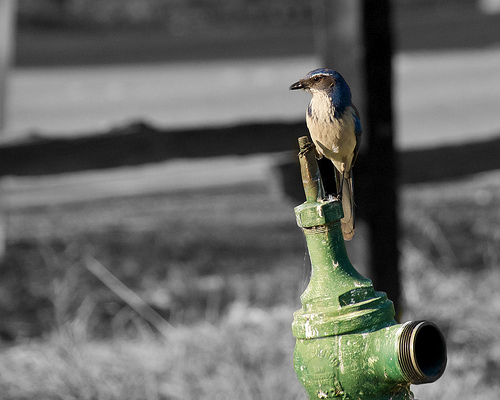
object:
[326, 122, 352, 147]
feathers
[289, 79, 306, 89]
beak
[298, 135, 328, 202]
nozzle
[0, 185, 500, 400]
grass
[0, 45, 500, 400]
ground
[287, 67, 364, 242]
bird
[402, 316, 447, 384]
space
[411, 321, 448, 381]
opening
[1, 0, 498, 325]
fence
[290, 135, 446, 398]
fire hydrant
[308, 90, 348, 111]
neck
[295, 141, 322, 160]
legs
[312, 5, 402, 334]
pole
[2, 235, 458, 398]
snow